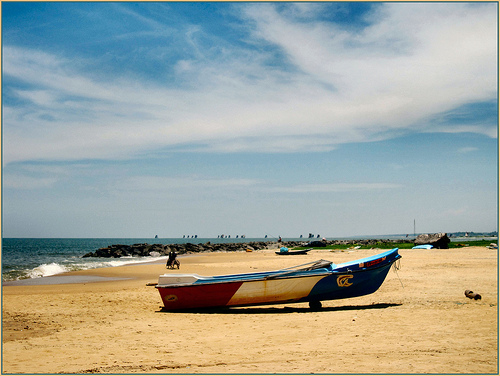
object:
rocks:
[81, 240, 310, 259]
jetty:
[0, 239, 306, 313]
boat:
[152, 245, 405, 312]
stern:
[151, 272, 203, 314]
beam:
[222, 267, 344, 315]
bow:
[306, 246, 403, 303]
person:
[277, 235, 281, 243]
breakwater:
[81, 237, 416, 261]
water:
[0, 237, 499, 285]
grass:
[291, 238, 498, 251]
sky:
[4, 4, 498, 238]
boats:
[154, 234, 159, 239]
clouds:
[3, 4, 499, 240]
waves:
[19, 250, 185, 282]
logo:
[336, 274, 354, 288]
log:
[464, 288, 482, 301]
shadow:
[154, 300, 406, 314]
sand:
[4, 246, 496, 375]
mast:
[413, 218, 416, 236]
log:
[307, 298, 323, 311]